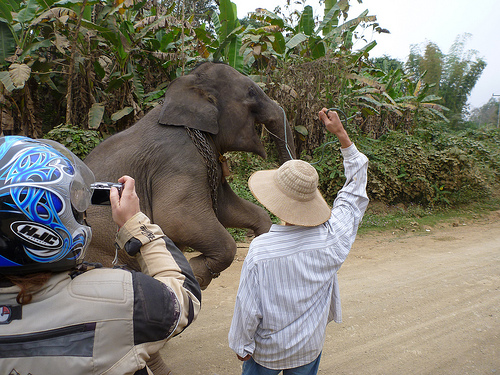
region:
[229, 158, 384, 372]
A blue and white striped shirt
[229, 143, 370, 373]
A long sleeve shirt.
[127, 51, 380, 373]
Man making elephant do a trick.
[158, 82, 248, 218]
Chain around elephant's neck.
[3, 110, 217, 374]
Person taking a picture of an elephant.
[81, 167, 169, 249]
Camera in person's right hand.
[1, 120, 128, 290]
Person wearing a helmet.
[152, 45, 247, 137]
Elephant's right ear.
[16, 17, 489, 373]
Two people on a dirt road.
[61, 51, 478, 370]
Elephant on a dirt road.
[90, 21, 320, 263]
A grey elephant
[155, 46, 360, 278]
A elephant with chains around it's neck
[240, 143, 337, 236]
A sun hat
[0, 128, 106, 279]
A black and blue helmet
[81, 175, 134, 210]
A camera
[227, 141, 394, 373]
A grey and white striped shirt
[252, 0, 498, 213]
Green foilage growing next to a dirt road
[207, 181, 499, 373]
A dirt road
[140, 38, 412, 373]
A man pulling a elephant with a rope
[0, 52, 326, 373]
A person taking a picture of an elephant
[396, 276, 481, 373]
The ground is dirt.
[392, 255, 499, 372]
The ground is tan.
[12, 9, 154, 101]
The plants are green.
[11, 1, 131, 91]
The plants have large leaves.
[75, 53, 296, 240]
The elephant is brown.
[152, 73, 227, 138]
The elephants has small ears.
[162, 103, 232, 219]
The elephants has a chain on it.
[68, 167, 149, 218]
A person is holding a camera.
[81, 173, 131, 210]
The camera is gray.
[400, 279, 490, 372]
The ground is made of dirt.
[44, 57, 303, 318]
a gray elephant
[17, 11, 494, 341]
a scene happening during the day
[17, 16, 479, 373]
a scene outside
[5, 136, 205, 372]
a person holding a camera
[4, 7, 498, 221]
a green bushes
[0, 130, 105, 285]
a blue helmet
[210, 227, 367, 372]
a person in the white striped shirt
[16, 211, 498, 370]
a dirt road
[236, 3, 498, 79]
a sky with white clouds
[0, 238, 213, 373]
a gray and tan shirt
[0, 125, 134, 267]
motorcycle helmet on person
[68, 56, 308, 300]
elephant with chains around neck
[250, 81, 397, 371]
hot weather clothing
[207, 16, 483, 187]
tropical vegetation with elephant in front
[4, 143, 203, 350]
taking picture of elephant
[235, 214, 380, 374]
stripped long sleeve dress shirt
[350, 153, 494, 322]
long dirt road in tropical area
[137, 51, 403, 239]
person capturing elephant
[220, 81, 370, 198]
rope around elephant nose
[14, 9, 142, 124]
trees and tall pants